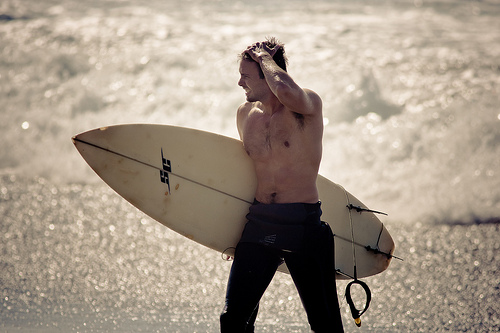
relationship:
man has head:
[218, 37, 346, 332] [237, 37, 287, 102]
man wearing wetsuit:
[218, 37, 346, 332] [221, 199, 345, 332]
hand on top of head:
[244, 40, 281, 60] [237, 37, 287, 102]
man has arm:
[218, 37, 346, 332] [259, 57, 320, 115]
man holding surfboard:
[218, 37, 346, 332] [70, 123, 396, 281]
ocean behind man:
[1, 0, 500, 331] [218, 37, 346, 332]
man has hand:
[218, 37, 346, 332] [244, 40, 281, 60]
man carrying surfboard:
[218, 37, 346, 332] [70, 123, 396, 281]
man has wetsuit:
[218, 37, 346, 332] [221, 199, 345, 332]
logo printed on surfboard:
[157, 147, 173, 193] [70, 123, 396, 281]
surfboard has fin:
[70, 123, 396, 281] [347, 203, 388, 217]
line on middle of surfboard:
[73, 136, 373, 247] [70, 123, 396, 281]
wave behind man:
[378, 210, 499, 229] [218, 37, 346, 332]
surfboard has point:
[70, 123, 396, 281] [71, 127, 92, 154]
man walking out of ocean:
[218, 37, 346, 332] [1, 0, 500, 331]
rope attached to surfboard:
[337, 180, 372, 326] [70, 123, 396, 281]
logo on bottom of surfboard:
[157, 147, 173, 193] [70, 123, 396, 281]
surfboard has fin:
[70, 123, 396, 281] [367, 244, 404, 262]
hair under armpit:
[291, 109, 306, 132] [286, 106, 318, 121]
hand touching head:
[244, 40, 281, 60] [237, 37, 287, 102]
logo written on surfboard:
[157, 147, 173, 193] [70, 123, 396, 281]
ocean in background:
[1, 0, 500, 331] [7, 2, 498, 228]